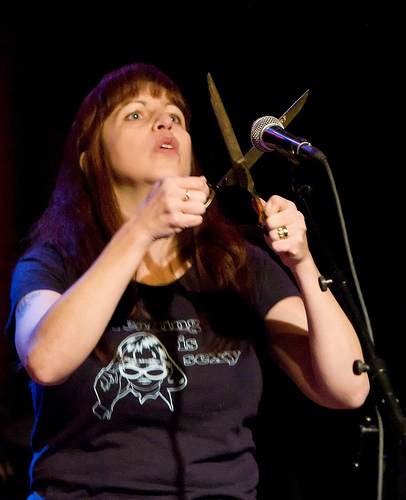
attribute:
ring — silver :
[277, 223, 293, 244]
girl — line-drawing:
[99, 338, 204, 453]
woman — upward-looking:
[6, 56, 346, 498]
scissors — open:
[178, 66, 320, 252]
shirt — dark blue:
[10, 207, 309, 499]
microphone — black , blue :
[248, 113, 326, 166]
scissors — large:
[201, 71, 309, 227]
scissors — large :
[190, 71, 311, 231]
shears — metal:
[186, 70, 300, 196]